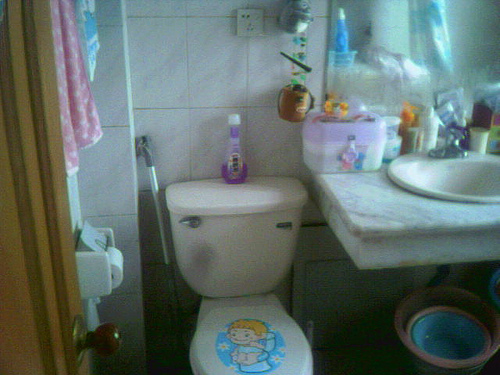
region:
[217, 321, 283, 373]
Picture of a child on a toilet lid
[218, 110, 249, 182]
Purple cleaning liquid on a toilet tank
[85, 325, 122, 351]
Handle of a wooden door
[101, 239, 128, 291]
Roll of toilet paper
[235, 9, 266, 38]
Outlet cover on the wall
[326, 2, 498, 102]
Mirror behind a sink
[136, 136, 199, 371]
Mop in corner of bathroom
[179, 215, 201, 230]
Handle on a toilet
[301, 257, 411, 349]
Vent under a sink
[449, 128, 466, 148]
Handle of a faucet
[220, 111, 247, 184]
Plastic bottle with purple liquid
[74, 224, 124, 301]
White plastic toilet paper holder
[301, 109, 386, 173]
White plastic container tote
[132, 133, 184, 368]
Aluminum cane with gray handle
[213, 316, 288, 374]
Little boy on toilet applique on toilet bowl cover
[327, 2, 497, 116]
Bathroom mirror on wall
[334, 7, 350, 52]
Bottle of blue liquid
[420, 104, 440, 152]
White bottle of lotion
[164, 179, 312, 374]
White ceramic toilet with silver handle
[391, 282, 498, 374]
Brown, tan, and blue pot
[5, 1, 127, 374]
brown wooden bathroom door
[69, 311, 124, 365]
gold and brown door knob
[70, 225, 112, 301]
white toilet paper holder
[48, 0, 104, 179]
pink towel on shower curtain rod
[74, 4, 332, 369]
white tile bathroom wall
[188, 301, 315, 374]
white toilet bowl lid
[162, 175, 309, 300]
white toilet water tank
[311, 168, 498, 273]
white bathroom sink counter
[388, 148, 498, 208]
white porcelain bathroom sink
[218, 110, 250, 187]
plastic bottle with purple liquid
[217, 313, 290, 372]
sticker of boy sitting on toilet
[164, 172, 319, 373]
white toilet in bathroom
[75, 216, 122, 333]
toilet paper and dispenser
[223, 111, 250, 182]
purple air freshener bottle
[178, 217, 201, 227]
metal toilet flusher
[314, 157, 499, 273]
marble sink counter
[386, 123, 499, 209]
sink in counter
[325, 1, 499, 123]
mirror on the wall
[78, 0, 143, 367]
white tiling on wall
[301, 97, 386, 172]
white and purple container on counter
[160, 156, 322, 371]
white toilet in a bathroom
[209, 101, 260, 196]
purple bottle on a toilet tank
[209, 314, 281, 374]
sticker of a boy on a toilet sit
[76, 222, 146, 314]
white toilet paper roll mounted on a bathroom wall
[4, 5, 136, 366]
brown bathroom door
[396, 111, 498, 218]
white sink on a bathroom counter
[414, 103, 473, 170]
silver sink faucet on a bathroom sink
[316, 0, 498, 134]
mirror on a bathroom wall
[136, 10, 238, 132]
white tiles on a bathroom wall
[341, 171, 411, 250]
white marble bathroom countertop